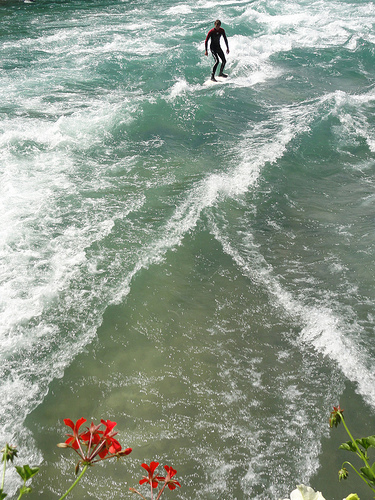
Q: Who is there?
A: A Person.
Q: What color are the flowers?
A: Red.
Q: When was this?
A: Daytime.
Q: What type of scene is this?
A: Outdoor.